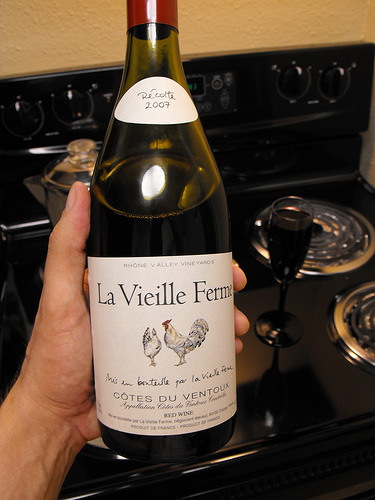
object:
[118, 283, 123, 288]
black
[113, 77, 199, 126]
label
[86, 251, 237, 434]
label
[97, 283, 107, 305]
letter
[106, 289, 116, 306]
letter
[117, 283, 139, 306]
letter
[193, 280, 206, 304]
letter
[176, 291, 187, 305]
letter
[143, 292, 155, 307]
letter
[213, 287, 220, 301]
letter